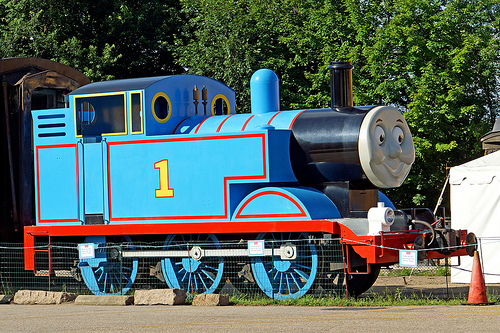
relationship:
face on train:
[357, 101, 417, 191] [30, 53, 486, 307]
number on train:
[150, 155, 177, 202] [30, 53, 486, 307]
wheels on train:
[70, 235, 330, 303] [30, 53, 486, 307]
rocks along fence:
[4, 279, 237, 317] [2, 232, 500, 306]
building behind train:
[437, 142, 499, 285] [30, 53, 486, 307]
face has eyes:
[357, 101, 417, 191] [367, 122, 407, 148]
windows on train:
[149, 81, 232, 129] [30, 53, 486, 307]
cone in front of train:
[451, 246, 495, 309] [30, 53, 486, 307]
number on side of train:
[150, 155, 177, 202] [30, 53, 486, 307]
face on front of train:
[357, 101, 417, 191] [30, 53, 486, 307]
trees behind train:
[1, 1, 499, 240] [30, 53, 486, 307]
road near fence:
[0, 299, 499, 329] [2, 232, 500, 306]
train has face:
[30, 53, 486, 307] [357, 101, 417, 191]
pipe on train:
[324, 60, 365, 114] [30, 53, 486, 307]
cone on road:
[451, 246, 495, 309] [0, 299, 499, 329]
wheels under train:
[70, 235, 330, 303] [30, 53, 486, 307]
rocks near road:
[4, 279, 237, 317] [0, 299, 499, 329]